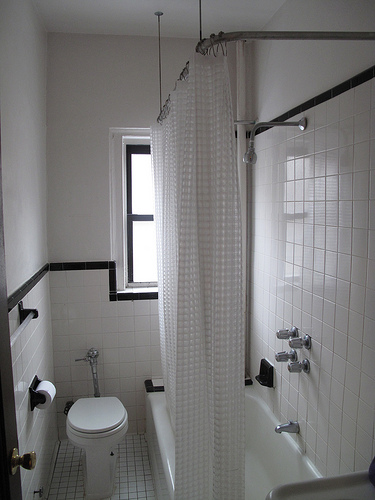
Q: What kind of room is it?
A: It is a bathroom.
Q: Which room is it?
A: It is a bathroom.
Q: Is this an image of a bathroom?
A: Yes, it is showing a bathroom.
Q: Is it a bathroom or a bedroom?
A: It is a bathroom.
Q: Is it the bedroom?
A: No, it is the bathroom.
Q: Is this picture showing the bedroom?
A: No, the picture is showing the bathroom.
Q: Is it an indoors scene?
A: Yes, it is indoors.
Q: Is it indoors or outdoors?
A: It is indoors.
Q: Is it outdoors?
A: No, it is indoors.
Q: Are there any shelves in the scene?
A: No, there are no shelves.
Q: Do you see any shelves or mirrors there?
A: No, there are no shelves or mirrors.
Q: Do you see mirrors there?
A: No, there are no mirrors.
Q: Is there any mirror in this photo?
A: No, there are no mirrors.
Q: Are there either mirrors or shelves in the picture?
A: No, there are no mirrors or shelves.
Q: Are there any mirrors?
A: No, there are no mirrors.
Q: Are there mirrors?
A: No, there are no mirrors.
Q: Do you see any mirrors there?
A: No, there are no mirrors.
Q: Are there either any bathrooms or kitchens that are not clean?
A: No, there is a bathroom but it is clean.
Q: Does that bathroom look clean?
A: Yes, the bathroom is clean.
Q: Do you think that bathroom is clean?
A: Yes, the bathroom is clean.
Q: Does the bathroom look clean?
A: Yes, the bathroom is clean.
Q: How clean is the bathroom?
A: The bathroom is clean.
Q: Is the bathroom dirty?
A: No, the bathroom is clean.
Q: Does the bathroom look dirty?
A: No, the bathroom is clean.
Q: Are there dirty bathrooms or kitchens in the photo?
A: No, there is a bathroom but it is clean.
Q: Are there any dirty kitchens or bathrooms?
A: No, there is a bathroom but it is clean.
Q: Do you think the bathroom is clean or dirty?
A: The bathroom is clean.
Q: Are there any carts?
A: No, there are no carts.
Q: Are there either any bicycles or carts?
A: No, there are no carts or bicycles.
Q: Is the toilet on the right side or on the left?
A: The toilet is on the left of the image.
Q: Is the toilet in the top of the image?
A: No, the toilet is in the bottom of the image.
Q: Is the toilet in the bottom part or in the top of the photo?
A: The toilet is in the bottom of the image.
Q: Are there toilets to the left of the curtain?
A: Yes, there is a toilet to the left of the curtain.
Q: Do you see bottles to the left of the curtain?
A: No, there is a toilet to the left of the curtain.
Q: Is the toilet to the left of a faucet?
A: No, the toilet is to the left of the curtain.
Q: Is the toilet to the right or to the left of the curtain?
A: The toilet is to the left of the curtain.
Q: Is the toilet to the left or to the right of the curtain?
A: The toilet is to the left of the curtain.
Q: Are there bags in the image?
A: No, there are no bags.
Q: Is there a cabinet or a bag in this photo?
A: No, there are no bags or cabinets.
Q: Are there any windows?
A: Yes, there is a window.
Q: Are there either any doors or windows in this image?
A: Yes, there is a window.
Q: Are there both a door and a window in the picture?
A: Yes, there are both a window and a door.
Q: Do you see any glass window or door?
A: Yes, there is a glass window.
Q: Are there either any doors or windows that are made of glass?
A: Yes, the window is made of glass.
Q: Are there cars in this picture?
A: No, there are no cars.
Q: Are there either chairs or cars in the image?
A: No, there are no cars or chairs.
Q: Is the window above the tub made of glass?
A: Yes, the window is made of glass.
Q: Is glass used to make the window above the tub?
A: Yes, the window is made of glass.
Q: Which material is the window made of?
A: The window is made of glass.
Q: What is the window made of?
A: The window is made of glass.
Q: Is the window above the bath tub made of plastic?
A: No, the window is made of glass.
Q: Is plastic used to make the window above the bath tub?
A: No, the window is made of glass.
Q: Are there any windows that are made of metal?
A: No, there is a window but it is made of glass.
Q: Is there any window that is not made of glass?
A: No, there is a window but it is made of glass.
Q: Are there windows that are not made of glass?
A: No, there is a window but it is made of glass.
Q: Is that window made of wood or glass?
A: The window is made of glass.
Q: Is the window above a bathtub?
A: Yes, the window is above a bathtub.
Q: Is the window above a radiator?
A: No, the window is above a bathtub.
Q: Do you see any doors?
A: Yes, there is a door.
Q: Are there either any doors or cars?
A: Yes, there is a door.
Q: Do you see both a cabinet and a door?
A: No, there is a door but no cabinets.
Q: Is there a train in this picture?
A: No, there are no trains.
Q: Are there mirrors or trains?
A: No, there are no trains or mirrors.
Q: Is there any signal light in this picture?
A: No, there are no traffic lights.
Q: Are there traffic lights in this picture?
A: No, there are no traffic lights.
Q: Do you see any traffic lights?
A: No, there are no traffic lights.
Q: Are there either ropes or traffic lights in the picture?
A: No, there are no traffic lights or ropes.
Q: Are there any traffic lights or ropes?
A: No, there are no traffic lights or ropes.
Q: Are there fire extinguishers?
A: No, there are no fire extinguishers.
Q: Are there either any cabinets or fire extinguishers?
A: No, there are no fire extinguishers or cabinets.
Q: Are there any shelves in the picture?
A: No, there are no shelves.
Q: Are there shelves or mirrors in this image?
A: No, there are no shelves or mirrors.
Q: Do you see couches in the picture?
A: No, there are no couches.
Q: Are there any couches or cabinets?
A: No, there are no couches or cabinets.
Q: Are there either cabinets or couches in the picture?
A: No, there are no couches or cabinets.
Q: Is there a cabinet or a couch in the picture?
A: No, there are no couches or cabinets.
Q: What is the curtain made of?
A: The curtain is made of plastic.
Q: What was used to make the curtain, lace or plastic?
A: The curtain is made of plastic.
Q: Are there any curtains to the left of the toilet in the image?
A: No, the curtain is to the right of the toilet.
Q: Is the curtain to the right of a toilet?
A: Yes, the curtain is to the right of a toilet.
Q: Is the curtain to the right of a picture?
A: No, the curtain is to the right of a toilet.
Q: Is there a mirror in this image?
A: No, there are no mirrors.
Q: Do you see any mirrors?
A: No, there are no mirrors.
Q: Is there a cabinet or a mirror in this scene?
A: No, there are no mirrors or cabinets.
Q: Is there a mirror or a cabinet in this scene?
A: No, there are no mirrors or cabinets.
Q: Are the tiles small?
A: Yes, the tiles are small.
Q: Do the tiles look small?
A: Yes, the tiles are small.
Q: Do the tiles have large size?
A: No, the tiles are small.